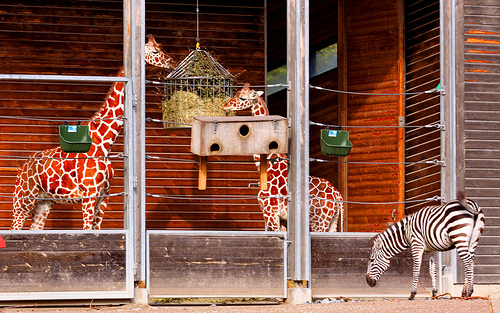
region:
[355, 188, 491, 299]
a zebra outside a giraffe pen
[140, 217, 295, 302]
a see through divider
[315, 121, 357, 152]
a green feeder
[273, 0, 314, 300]
a tall post at a giraffe pen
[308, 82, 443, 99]
a cable running between posts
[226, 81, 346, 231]
a small giraffe eating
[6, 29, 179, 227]
a tall giraffe in a pen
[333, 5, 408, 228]
a wall made of wood slats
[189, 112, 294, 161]
a rectangular box with three holes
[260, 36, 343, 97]
windows in a giraffe pen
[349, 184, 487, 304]
A ZEBRA SWISHING IT'S TAIL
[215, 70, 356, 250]
A YOUNG GIRAFFE IN A CAGE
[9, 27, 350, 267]
TWO GIRAFFES IN A CAGE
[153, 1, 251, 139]
A HANGING FEEDER WITH HAY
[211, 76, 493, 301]
A GIRAFFE AND A ZEBRA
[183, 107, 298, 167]
A WOODEN BOX WITH THREE HOLES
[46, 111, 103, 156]
A PLASTIC GREEN CONTAINER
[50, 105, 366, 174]
TWO PLASTIC GREEN CONTAINERS AND A WOODEN BOX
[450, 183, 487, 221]
A ZEBRA'S TAIL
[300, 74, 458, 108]
A METAL CABLE ON A CAGE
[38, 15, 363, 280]
giraffes inside an enclosure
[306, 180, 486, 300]
zebra standing outside giraffes' enclosure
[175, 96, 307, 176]
rectangular wooden box with holes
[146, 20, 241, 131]
wire basket with domed top filled with hay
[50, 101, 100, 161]
green container hanging from a wire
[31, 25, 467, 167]
horizontal lines inside of enclosure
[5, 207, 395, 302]
low panels on the open wall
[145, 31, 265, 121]
tall and shorter giraffe at feeder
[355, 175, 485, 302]
zebra bending down to look at opening under partition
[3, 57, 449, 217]
wires across the open wall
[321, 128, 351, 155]
Green food bin on a wire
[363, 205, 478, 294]
Zebra bending its head over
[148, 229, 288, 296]
Glass panel on a cage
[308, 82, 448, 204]
Wire's making up a cage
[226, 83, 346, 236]
Giraffe with head facing left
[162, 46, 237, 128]
Animal food in a hanging cage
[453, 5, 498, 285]
Wooden panel on a cage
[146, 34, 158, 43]
Horns on a giraffe's head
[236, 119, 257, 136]
Hole in a wooden box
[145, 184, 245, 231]
Animal shadows on a wall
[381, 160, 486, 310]
the zebra has stripes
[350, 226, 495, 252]
the zebra has stripes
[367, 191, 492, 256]
the zebra has stripes